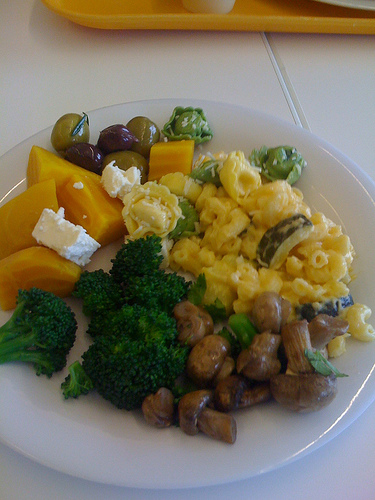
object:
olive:
[98, 126, 138, 155]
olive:
[52, 114, 90, 150]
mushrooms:
[141, 386, 177, 422]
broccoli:
[2, 289, 78, 373]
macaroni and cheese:
[291, 271, 328, 301]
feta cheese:
[30, 207, 100, 260]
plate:
[0, 98, 373, 491]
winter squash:
[121, 178, 179, 240]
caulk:
[261, 33, 301, 128]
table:
[0, 1, 373, 500]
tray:
[43, 2, 373, 34]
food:
[1, 107, 374, 445]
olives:
[101, 149, 147, 178]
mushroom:
[176, 390, 238, 445]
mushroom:
[185, 333, 238, 381]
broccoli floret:
[61, 361, 93, 399]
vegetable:
[254, 215, 319, 270]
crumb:
[73, 182, 83, 191]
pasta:
[161, 106, 214, 144]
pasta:
[253, 144, 307, 184]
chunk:
[148, 141, 194, 180]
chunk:
[57, 170, 128, 245]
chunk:
[1, 246, 83, 311]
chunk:
[0, 178, 64, 262]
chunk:
[27, 145, 100, 192]